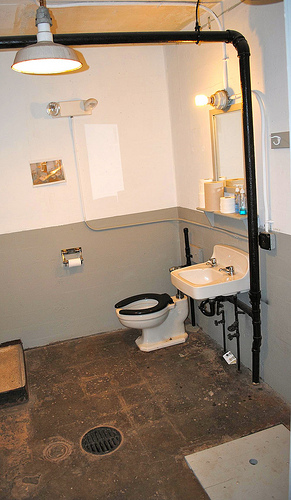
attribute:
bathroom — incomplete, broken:
[1, 1, 288, 500]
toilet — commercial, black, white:
[113, 228, 190, 352]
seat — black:
[114, 291, 174, 316]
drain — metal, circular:
[77, 426, 123, 458]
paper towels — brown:
[201, 181, 223, 211]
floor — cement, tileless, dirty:
[0, 320, 291, 499]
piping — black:
[0, 29, 262, 385]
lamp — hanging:
[10, 0, 84, 75]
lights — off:
[47, 97, 99, 120]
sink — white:
[169, 242, 250, 302]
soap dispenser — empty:
[235, 187, 248, 216]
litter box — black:
[0, 339, 27, 405]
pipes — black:
[199, 298, 255, 374]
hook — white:
[271, 132, 283, 146]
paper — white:
[221, 349, 240, 367]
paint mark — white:
[85, 126, 125, 201]